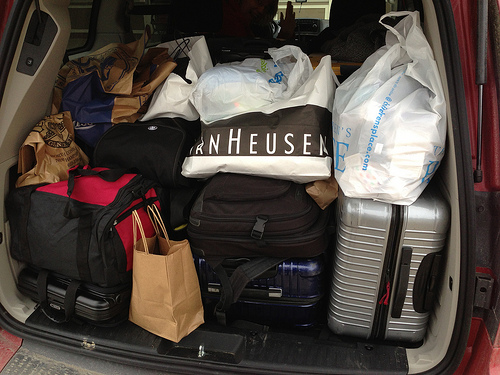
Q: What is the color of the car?
A: Red.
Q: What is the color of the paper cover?
A: Brown.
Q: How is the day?
A: Sunny.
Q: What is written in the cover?
A: Van Heusen.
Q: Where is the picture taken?
A: The trunk of a car.